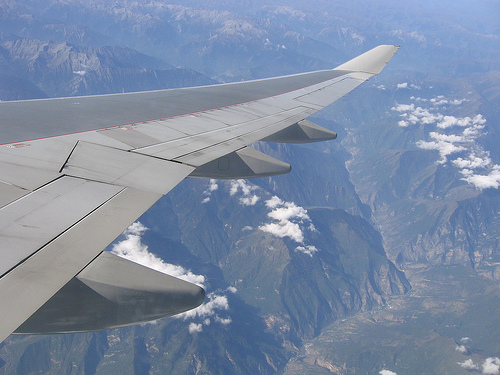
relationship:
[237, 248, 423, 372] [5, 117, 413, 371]
valley in hills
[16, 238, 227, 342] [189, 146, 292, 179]
propellers on bottom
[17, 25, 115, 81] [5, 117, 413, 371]
sun on hills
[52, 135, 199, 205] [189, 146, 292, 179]
spoiler on bottom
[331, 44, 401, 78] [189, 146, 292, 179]
tip of bottom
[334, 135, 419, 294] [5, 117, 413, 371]
chasm in hills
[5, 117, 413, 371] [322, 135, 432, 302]
hills with river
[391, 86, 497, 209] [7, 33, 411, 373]
formation below jet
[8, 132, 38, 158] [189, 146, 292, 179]
light on bottom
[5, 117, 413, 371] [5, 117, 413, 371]
hills of hills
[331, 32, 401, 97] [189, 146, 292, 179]
tip of bottom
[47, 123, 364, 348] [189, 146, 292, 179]
bottom of bottom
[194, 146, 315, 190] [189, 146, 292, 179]
bottom of bottom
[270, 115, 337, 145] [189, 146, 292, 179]
bottom of bottom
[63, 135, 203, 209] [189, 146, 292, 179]
flap on bottom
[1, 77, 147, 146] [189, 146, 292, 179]
front on bottom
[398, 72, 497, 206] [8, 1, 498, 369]
clouds in sky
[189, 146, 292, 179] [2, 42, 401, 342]
bottom on airplane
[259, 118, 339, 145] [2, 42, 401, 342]
engine on airplane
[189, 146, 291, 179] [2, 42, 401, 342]
engine on airplane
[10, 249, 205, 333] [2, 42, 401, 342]
engine on airplane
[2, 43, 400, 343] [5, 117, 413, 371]
airplane flying over hills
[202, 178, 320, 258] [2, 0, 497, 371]
snow on mountain top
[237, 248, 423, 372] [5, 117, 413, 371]
valley beneath hills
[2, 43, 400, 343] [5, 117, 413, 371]
airplane flying high over hills